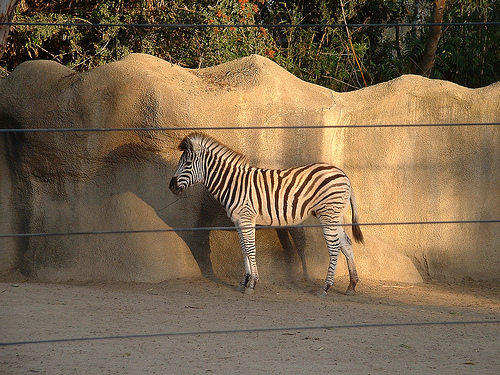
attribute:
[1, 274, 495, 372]
ground — dirt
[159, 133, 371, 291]
zebra — black, white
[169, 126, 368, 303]
zebra — standing on dirt